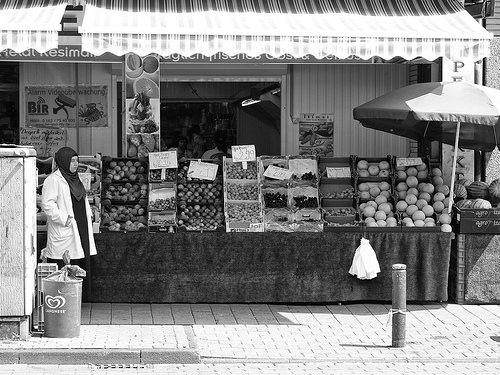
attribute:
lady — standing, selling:
[42, 146, 96, 301]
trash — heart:
[40, 276, 83, 341]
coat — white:
[41, 166, 97, 260]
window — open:
[159, 62, 283, 157]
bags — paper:
[349, 231, 383, 280]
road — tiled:
[7, 363, 499, 375]